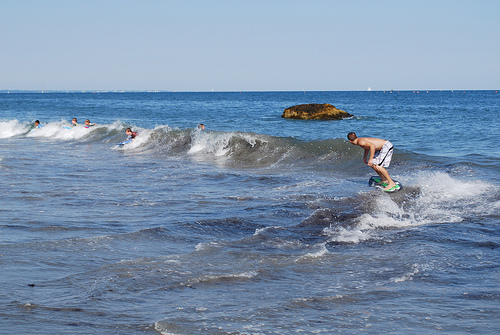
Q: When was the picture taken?
A: During the day.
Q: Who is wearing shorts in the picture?
A: A boy.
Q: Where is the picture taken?
A: By the ocean.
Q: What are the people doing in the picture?
A: Surfing.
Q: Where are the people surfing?
A: In the ocean.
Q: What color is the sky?
A: Blue.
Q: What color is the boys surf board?
A: Green.